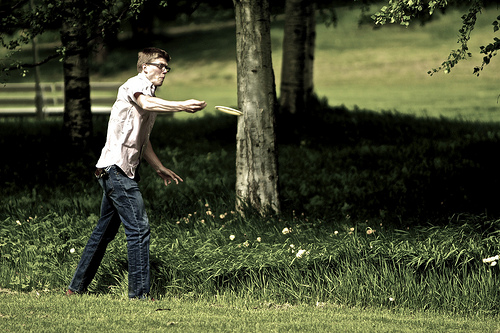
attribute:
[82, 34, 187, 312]
man — strained, skinny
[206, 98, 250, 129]
frisbee — yellow, mid air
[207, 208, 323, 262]
flowers — white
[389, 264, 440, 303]
grass — green, tall, thick, cut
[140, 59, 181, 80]
glasses — black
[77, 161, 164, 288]
blue jeans — long, acid wash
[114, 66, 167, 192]
shirt — button up, white, short sleeve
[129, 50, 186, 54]
brown hair — short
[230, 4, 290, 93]
trunk — big, small, brown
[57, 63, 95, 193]
tree — brown, tall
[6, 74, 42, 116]
fence — picket, white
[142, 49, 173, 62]
hair — brown